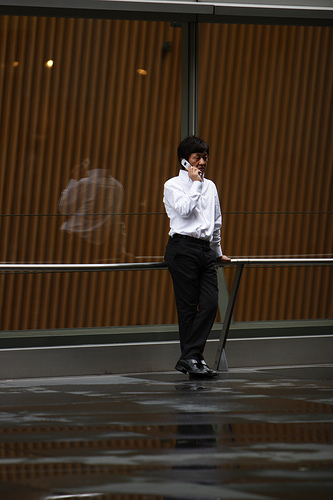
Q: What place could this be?
A: It is a road.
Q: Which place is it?
A: It is a road.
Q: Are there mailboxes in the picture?
A: No, there are no mailboxes.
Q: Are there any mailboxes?
A: No, there are no mailboxes.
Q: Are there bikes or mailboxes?
A: No, there are no mailboxes or bikes.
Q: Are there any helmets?
A: No, there are no helmets.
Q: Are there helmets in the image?
A: No, there are no helmets.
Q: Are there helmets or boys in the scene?
A: No, there are no helmets or boys.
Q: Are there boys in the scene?
A: No, there are no boys.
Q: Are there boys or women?
A: No, there are no boys or women.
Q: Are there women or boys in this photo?
A: No, there are no boys or women.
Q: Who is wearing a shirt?
A: The man is wearing a shirt.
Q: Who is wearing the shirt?
A: The man is wearing a shirt.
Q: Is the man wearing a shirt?
A: Yes, the man is wearing a shirt.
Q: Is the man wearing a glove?
A: No, the man is wearing a shirt.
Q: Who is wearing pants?
A: The man is wearing pants.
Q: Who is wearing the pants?
A: The man is wearing pants.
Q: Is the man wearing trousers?
A: Yes, the man is wearing trousers.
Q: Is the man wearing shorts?
A: No, the man is wearing trousers.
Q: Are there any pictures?
A: No, there are no pictures.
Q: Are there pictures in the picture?
A: No, there are no pictures.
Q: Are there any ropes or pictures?
A: No, there are no pictures or ropes.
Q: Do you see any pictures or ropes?
A: No, there are no pictures or ropes.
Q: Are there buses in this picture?
A: No, there are no buses.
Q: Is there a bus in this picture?
A: No, there are no buses.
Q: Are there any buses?
A: No, there are no buses.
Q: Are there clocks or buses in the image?
A: No, there are no buses or clocks.